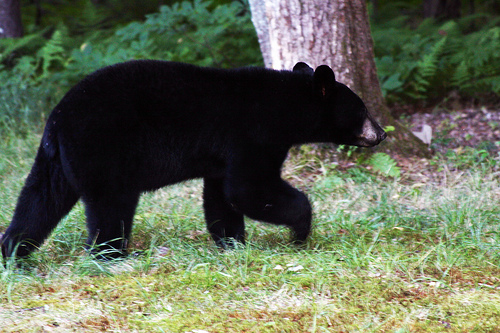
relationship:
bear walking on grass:
[104, 87, 377, 239] [378, 253, 395, 283]